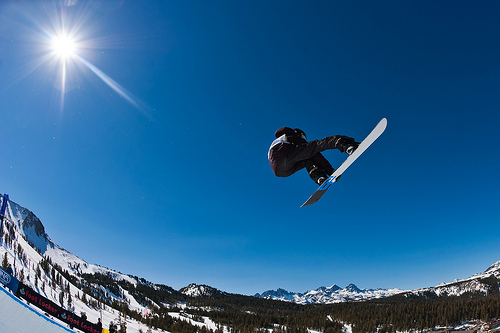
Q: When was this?
A: Daytime.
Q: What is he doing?
A: A stunt.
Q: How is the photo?
A: Clear.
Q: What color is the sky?
A: Blue.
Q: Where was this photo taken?
A: On the ski slope.